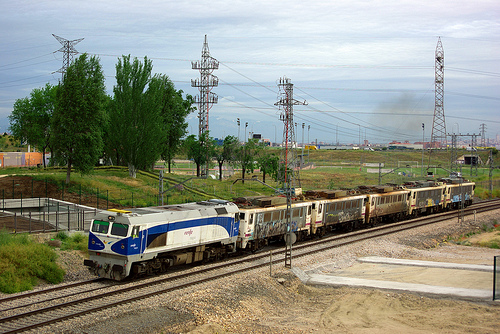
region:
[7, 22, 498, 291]
utility poles and wires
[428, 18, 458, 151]
utility tower in background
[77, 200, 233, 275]
white and blue front train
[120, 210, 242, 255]
bold blue swirl on white background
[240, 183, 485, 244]
5 silver train cars in back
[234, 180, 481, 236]
train cars covered with graffiti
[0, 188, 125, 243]
gray tunnel under grass area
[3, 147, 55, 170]
orange building next to trees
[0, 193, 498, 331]
brown gravel between tracks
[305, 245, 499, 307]
two long gray concrete slabs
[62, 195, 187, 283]
a train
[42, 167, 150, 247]
a train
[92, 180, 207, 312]
a train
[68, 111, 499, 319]
train on a track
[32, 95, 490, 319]
track with trains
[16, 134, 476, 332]
a short train on the tracks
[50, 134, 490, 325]
tracks with a short train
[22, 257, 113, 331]
two train tracks next to each other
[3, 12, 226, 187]
tall trees with leaves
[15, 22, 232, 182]
tall trees with green leaves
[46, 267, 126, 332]
rocks surround the tracks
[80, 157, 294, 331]
a blue and gray train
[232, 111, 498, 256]
train cars that are holding stuff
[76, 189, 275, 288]
Blue and white train engine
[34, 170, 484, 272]
Five train cars behind engine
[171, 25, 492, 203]
Power transmission lines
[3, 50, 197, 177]
A group of bright green trees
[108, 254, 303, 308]
Gravel and dirt surrounding tracks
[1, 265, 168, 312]
Pair of train tracks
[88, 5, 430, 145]
Blue sky with white clouds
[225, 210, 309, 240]
Graffiti on the side of rail car.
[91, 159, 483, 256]
A commuter train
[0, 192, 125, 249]
A concrete opening leading underground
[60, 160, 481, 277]
A train on a track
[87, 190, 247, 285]
A blue and white train track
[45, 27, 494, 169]
Power lines in the distance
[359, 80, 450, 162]
Smoke in the distance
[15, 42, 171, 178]
Trees on a hill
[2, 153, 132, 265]
Tunnel in the side of a hill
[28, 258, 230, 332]
Two sets of train tracks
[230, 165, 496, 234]
Five train cars in a row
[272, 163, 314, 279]
Metal pole next to train track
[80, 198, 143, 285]
Front of a train engine